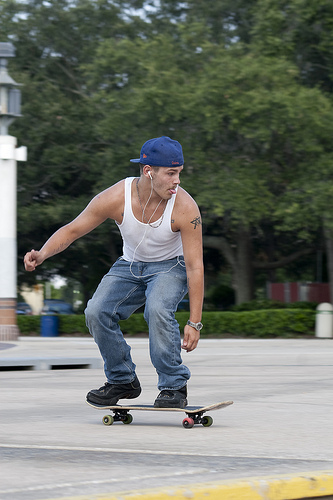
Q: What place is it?
A: It is a sidewalk.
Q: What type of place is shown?
A: It is a sidewalk.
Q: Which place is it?
A: It is a sidewalk.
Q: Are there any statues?
A: No, there are no statues.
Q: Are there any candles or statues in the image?
A: No, there are no statues or candles.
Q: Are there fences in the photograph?
A: No, there are no fences.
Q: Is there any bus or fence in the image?
A: No, there are no fences or buses.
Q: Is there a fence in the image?
A: No, there are no fences.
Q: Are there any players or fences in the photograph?
A: No, there are no fences or players.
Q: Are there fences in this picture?
A: No, there are no fences.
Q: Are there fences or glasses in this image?
A: No, there are no fences or glasses.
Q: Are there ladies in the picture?
A: No, there are no ladies.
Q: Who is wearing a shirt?
A: The boy is wearing a shirt.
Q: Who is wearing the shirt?
A: The boy is wearing a shirt.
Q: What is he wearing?
A: The boy is wearing a shirt.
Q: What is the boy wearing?
A: The boy is wearing a shirt.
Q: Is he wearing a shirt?
A: Yes, the boy is wearing a shirt.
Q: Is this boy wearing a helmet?
A: No, the boy is wearing a shirt.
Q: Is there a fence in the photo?
A: No, there are no fences.